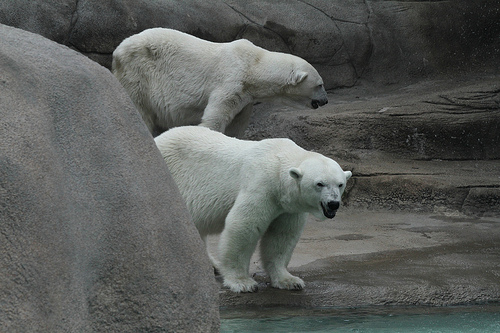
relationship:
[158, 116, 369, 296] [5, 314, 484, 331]
bear facing camera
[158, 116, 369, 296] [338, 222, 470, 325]
bear facing right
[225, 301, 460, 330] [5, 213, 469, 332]
water in foreground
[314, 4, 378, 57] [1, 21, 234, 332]
crack in boulder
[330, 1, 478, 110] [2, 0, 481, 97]
boulder in background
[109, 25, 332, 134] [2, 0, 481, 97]
bears in background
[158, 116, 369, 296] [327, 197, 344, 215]
bear has nose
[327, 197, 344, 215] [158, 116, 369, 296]
nose of bear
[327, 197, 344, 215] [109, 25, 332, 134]
nose of bears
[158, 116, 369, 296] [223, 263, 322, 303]
bear has paws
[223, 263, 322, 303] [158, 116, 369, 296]
paws of bear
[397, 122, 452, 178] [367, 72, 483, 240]
spots on rock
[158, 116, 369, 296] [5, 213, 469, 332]
bear in foreground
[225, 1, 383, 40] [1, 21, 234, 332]
cracks in boulder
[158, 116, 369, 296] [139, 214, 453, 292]
bear standing on rocks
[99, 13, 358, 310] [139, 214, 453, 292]
bears standing on rocks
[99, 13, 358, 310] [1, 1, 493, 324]
bears in area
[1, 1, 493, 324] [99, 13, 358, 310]
area with bears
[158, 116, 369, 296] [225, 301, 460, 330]
bear near water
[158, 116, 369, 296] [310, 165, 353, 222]
bear with face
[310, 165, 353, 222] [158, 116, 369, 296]
face of bear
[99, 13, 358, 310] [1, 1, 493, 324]
bears in pen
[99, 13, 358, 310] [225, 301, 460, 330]
polar bears near water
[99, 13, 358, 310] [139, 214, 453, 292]
bears near rocks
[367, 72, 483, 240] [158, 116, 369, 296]
rock in front of bear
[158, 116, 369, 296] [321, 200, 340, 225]
bear with mouth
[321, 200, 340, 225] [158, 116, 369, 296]
mouth of bear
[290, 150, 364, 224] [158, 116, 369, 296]
head of bear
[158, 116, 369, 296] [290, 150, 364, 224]
bear with head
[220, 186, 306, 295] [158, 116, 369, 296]
legs of bear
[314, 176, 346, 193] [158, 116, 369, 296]
eyes of bear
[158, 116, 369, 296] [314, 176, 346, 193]
bear has eyes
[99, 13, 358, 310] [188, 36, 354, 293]
bears in positions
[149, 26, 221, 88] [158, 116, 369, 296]
back of bear